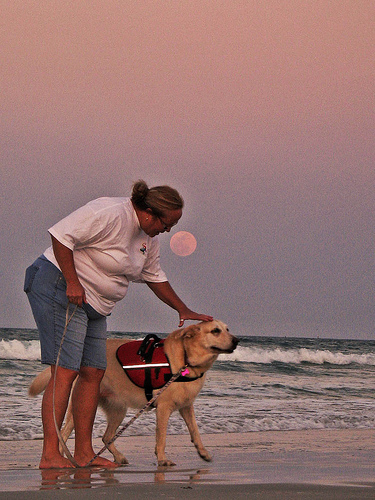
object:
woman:
[24, 177, 214, 469]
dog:
[27, 319, 236, 464]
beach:
[0, 426, 374, 498]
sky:
[0, 0, 374, 340]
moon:
[169, 229, 198, 257]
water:
[0, 326, 374, 440]